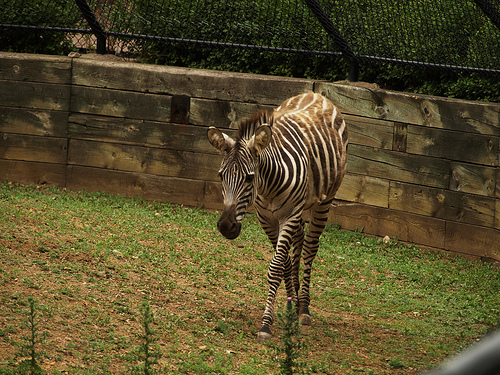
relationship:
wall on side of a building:
[0, 54, 500, 263] [1, 7, 480, 235]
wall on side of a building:
[5, 56, 71, 176] [1, 7, 480, 235]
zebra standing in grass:
[204, 92, 353, 338] [90, 210, 270, 372]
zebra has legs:
[204, 92, 353, 338] [255, 207, 334, 335]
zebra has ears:
[204, 92, 353, 338] [206, 123, 274, 150]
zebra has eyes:
[204, 92, 353, 338] [216, 168, 259, 185]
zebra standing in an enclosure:
[204, 92, 353, 338] [3, 3, 484, 367]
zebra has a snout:
[204, 92, 353, 338] [215, 203, 243, 240]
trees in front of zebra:
[23, 289, 301, 372] [204, 92, 353, 338]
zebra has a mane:
[204, 92, 353, 338] [226, 114, 269, 165]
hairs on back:
[260, 112, 298, 119] [266, 90, 318, 139]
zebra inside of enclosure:
[204, 92, 353, 338] [3, 3, 484, 367]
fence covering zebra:
[4, 2, 484, 78] [204, 88, 352, 338]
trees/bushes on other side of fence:
[108, 0, 449, 76] [4, 2, 484, 78]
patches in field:
[16, 227, 188, 306] [1, 184, 483, 371]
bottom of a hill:
[341, 232, 469, 366] [1, 184, 204, 364]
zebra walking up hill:
[204, 92, 353, 338] [0, 181, 401, 372]